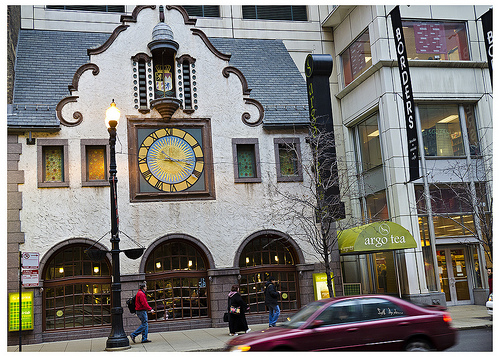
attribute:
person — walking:
[131, 277, 278, 342]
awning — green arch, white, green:
[333, 223, 420, 255]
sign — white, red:
[23, 252, 40, 289]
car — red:
[231, 292, 461, 347]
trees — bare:
[265, 113, 490, 325]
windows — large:
[337, 23, 490, 301]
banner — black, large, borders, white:
[390, 5, 426, 186]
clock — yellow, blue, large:
[131, 119, 215, 201]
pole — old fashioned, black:
[111, 102, 135, 349]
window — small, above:
[230, 135, 262, 189]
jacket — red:
[133, 293, 159, 313]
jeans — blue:
[128, 311, 153, 347]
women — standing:
[225, 287, 251, 333]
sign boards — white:
[315, 271, 337, 303]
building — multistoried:
[4, 2, 490, 345]